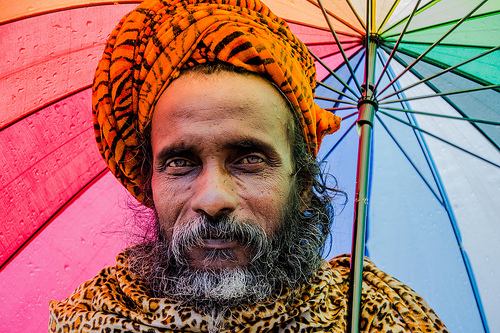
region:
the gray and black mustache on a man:
[167, 218, 268, 264]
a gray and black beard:
[112, 186, 334, 300]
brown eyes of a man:
[162, 152, 265, 169]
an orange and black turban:
[92, 0, 340, 207]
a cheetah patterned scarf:
[50, 248, 450, 330]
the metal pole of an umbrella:
[344, 31, 379, 331]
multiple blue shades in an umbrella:
[313, 40, 495, 332]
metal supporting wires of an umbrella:
[283, 0, 498, 180]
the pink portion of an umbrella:
[2, 170, 158, 331]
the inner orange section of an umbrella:
[265, 1, 367, 38]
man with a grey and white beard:
[102, 4, 371, 311]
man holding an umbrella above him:
[32, 9, 489, 327]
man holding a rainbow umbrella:
[13, 13, 484, 320]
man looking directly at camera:
[75, 0, 356, 323]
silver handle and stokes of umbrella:
[332, 0, 476, 327]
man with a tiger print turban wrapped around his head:
[100, 4, 340, 305]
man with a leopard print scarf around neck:
[58, 248, 443, 330]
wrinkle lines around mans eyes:
[154, 131, 291, 195]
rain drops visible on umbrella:
[0, 14, 79, 216]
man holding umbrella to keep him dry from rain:
[16, 29, 463, 324]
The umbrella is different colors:
[3, 2, 495, 319]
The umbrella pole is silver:
[307, 3, 470, 330]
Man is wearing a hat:
[90, 1, 336, 294]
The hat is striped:
[92, 2, 332, 204]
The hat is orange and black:
[91, 0, 333, 198]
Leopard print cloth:
[43, 258, 443, 331]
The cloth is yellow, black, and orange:
[43, 249, 449, 330]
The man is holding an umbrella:
[1, 0, 496, 327]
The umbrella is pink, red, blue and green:
[4, 2, 498, 319]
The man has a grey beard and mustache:
[144, 55, 324, 309]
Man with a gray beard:
[136, 167, 334, 290]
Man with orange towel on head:
[77, 29, 284, 105]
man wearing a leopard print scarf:
[53, 238, 320, 331]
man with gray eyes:
[161, 129, 278, 174]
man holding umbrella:
[38, 10, 463, 140]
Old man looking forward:
[130, 141, 315, 278]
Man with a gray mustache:
[156, 230, 282, 307]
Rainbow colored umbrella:
[328, 70, 490, 285]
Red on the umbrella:
[11, 77, 121, 288]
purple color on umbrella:
[55, 206, 147, 271]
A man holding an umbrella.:
[49, 45, 398, 277]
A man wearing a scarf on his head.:
[54, 34, 324, 144]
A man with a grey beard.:
[118, 192, 315, 308]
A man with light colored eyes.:
[134, 140, 299, 167]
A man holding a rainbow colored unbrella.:
[136, 70, 442, 258]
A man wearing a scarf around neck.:
[108, 276, 418, 331]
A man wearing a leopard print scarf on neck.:
[85, 256, 355, 331]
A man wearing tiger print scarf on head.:
[101, 33, 297, 104]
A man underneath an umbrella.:
[46, 55, 416, 266]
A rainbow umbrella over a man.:
[56, 23, 446, 302]